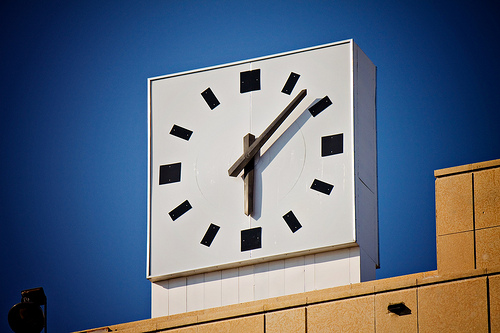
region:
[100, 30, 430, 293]
this is a clock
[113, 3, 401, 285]
the clock is square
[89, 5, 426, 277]
the clock is white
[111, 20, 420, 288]
the clock has a square face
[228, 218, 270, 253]
the hours are marked by squares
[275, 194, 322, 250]
these hours are marked by rectangles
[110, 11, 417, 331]
the clock is on a roof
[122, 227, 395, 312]
this is the base of the clock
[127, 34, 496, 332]
Large clock on building ledge.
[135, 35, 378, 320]
Clock is white with black marks for numbers.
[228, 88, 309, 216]
Clock has two black hands.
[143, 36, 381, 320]
The time on the clock is 6:08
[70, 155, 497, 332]
Ledge is made up of brown blocks.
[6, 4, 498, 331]
Behind the clock the color is a bright blue.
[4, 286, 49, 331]
There is a statue on the wall by the clock.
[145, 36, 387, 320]
The clock is very large in appearance.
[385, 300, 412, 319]
There is a black item coming out of a brown block on the ledge.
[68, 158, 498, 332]
The ledge has two levels.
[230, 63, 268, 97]
The square is black.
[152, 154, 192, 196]
The square is black.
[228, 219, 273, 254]
The square is black.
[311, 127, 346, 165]
The square is black.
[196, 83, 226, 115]
The rectanlge is black.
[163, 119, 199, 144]
The rectanlge is black.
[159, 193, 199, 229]
The rectanlge is black.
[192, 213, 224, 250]
The rectanlge is black.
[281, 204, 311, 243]
The rectanlge is black.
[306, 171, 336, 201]
The rectanlge is black.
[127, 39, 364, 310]
large modern styled clock on a building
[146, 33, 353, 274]
a square clock on a rock ledge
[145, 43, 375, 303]
a white clock face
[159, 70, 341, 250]
rectangles and squares represent numbers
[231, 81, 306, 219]
grey clock hands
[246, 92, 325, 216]
shadows of the clock hands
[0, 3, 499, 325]
a deep blue colored sky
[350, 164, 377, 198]
construction seam of the clock sides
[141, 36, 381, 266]
square white clock face with black hands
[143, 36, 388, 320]
square white clock sitting on a pedestal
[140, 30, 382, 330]
square white clock sitting on a tan shelf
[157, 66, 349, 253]
black rectangles on the face of a white clock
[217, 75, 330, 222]
The hands on the clock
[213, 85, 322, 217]
A set of hands on the clock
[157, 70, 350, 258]
The face of the clock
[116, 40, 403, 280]
The clock on top the building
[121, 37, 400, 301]
A clock on top the building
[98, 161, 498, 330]
The tan building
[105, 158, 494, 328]
A tan building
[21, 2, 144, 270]
Blue sky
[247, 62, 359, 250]
Right half of clock face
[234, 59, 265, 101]
Black box in 12 o' clock position on clock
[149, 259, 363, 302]
base of clock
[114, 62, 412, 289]
clock on the wall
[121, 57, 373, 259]
clock has a white face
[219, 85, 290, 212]
clock has brown hands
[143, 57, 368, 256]
clock has black spots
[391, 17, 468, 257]
wall is blue in color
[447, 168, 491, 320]
tile is brown in color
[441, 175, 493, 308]
part of wall is tile